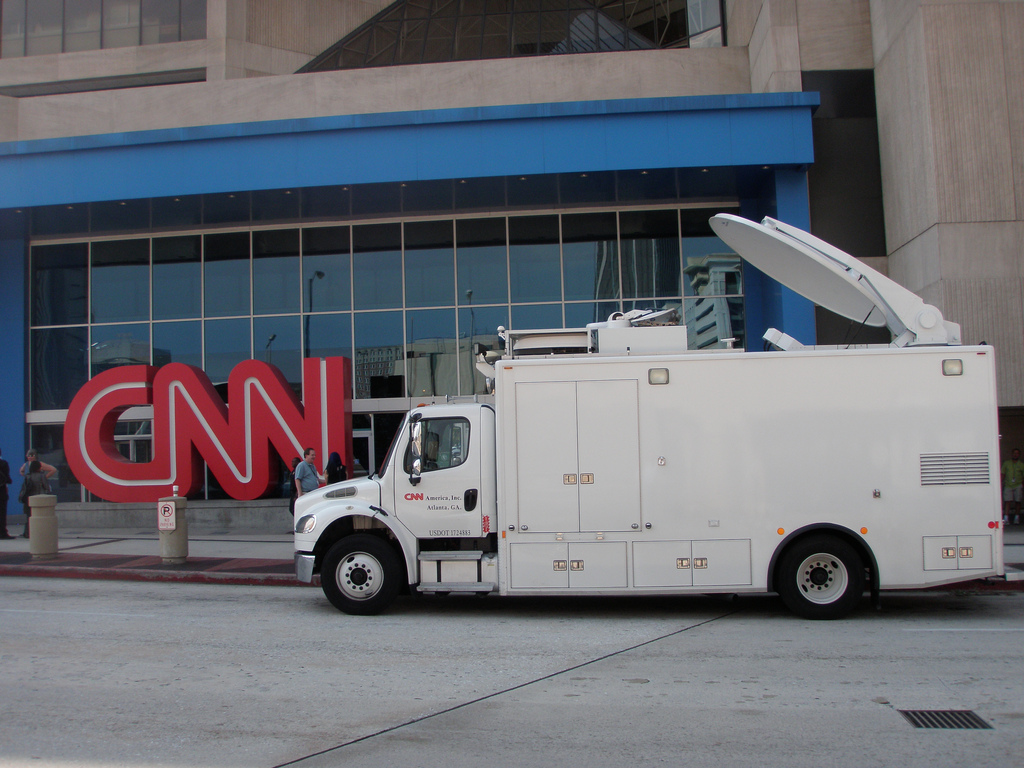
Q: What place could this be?
A: It is an entrance.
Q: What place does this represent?
A: It represents the entrance.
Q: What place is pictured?
A: It is an entrance.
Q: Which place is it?
A: It is an entrance.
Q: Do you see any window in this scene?
A: Yes, there is a window.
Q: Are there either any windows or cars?
A: Yes, there is a window.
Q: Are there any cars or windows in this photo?
A: Yes, there is a window.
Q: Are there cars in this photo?
A: No, there are no cars.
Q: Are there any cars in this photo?
A: No, there are no cars.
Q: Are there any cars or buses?
A: No, there are no cars or buses.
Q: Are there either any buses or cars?
A: No, there are no cars or buses.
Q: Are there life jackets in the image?
A: No, there are no life jackets.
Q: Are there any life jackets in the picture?
A: No, there are no life jackets.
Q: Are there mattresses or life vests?
A: No, there are no life vests or mattresses.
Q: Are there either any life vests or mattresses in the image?
A: No, there are no life vests or mattresses.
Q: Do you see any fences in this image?
A: No, there are no fences.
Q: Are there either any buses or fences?
A: No, there are no fences or buses.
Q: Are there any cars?
A: No, there are no cars.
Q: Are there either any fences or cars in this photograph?
A: No, there are no cars or fences.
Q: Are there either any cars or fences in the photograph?
A: No, there are no cars or fences.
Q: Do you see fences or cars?
A: No, there are no cars or fences.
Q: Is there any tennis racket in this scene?
A: No, there are no rackets.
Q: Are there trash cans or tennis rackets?
A: No, there are no tennis rackets or trash cans.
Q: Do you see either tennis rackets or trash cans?
A: No, there are no tennis rackets or trash cans.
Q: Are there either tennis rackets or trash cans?
A: No, there are no tennis rackets or trash cans.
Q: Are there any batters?
A: No, there are no batters.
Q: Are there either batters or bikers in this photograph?
A: No, there are no batters or bikers.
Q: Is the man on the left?
A: Yes, the man is on the left of the image.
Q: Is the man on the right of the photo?
A: No, the man is on the left of the image.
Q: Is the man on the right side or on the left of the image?
A: The man is on the left of the image.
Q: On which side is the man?
A: The man is on the left of the image.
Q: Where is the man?
A: The man is on the pavement.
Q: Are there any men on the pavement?
A: Yes, there is a man on the pavement.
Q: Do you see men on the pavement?
A: Yes, there is a man on the pavement.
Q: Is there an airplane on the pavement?
A: No, there is a man on the pavement.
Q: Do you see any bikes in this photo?
A: No, there are no bikes.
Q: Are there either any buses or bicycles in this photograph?
A: No, there are no bicycles or buses.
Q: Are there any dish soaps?
A: No, there are no dish soaps.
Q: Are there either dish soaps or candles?
A: No, there are no dish soaps or candles.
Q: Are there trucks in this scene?
A: Yes, there is a truck.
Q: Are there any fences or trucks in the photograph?
A: Yes, there is a truck.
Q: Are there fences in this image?
A: No, there are no fences.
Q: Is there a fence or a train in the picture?
A: No, there are no fences or trains.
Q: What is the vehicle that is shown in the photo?
A: The vehicle is a truck.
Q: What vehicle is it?
A: The vehicle is a truck.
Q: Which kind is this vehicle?
A: This is a truck.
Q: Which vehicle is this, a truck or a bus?
A: This is a truck.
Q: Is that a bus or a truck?
A: That is a truck.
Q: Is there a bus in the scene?
A: No, there are no buses.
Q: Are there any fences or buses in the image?
A: No, there are no buses or fences.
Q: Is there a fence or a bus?
A: No, there are no buses or fences.